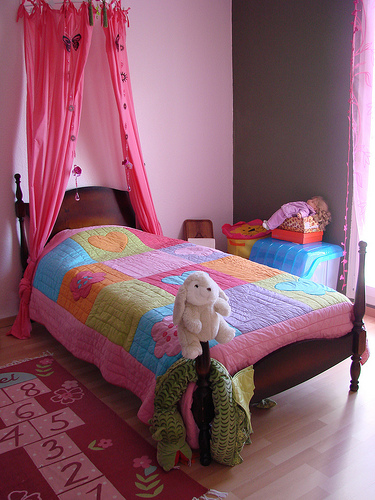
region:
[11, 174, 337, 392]
bed for a girl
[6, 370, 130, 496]
hopscotch pattern on carpet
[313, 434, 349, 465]
the floor is wood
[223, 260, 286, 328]
blanket on the bed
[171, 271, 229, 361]
bunny on the bed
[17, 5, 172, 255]
canopy over the bed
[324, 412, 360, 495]
reflection on the floor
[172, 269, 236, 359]
Stuffed rabbit on the bed leg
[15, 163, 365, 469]
Bed set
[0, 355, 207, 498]
Dark red carpet with several numbers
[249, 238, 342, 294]
Small toy box next to the bed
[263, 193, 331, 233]
Stuffed toys on top of the toy box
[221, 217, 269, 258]
Yellow basket next to the toy box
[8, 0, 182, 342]
Pink curtain on top of the bed head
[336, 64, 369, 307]
Window next to the bed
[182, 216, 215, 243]
Wooden chair next to the bed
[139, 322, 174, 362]
square on the quilt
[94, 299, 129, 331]
square on the quilt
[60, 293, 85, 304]
square on the quilt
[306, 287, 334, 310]
square on the quilt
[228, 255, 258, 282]
square on the quilt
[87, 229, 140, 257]
square on the quilt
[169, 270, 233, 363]
the bunny on the bed leg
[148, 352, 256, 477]
the stuffed animal in the frame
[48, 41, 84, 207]
the beads hanging from the ceiling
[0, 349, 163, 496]
the rug on the ground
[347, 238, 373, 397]
the wooden leg of the bed frame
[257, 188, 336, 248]
the doll on the shoebox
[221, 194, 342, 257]
the toys in th corner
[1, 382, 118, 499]
the numbers on the rug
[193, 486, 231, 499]
the white frills on the edgde of the rug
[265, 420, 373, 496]
the wooden floorboards for the room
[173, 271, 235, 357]
A white, stuffed bunny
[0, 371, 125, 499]
A hopscotch pattern on a rug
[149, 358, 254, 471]
A green, stuffed dragon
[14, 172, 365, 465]
A bed with a dark-brown, wooden frame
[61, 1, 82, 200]
A string of adornments hanging from the ceiling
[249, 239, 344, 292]
A plastic container with a blue lid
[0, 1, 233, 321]
A light pink wall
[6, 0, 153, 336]
Hot pink drapes above the bed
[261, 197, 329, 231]
A toy doll with light brown hair and pink clothes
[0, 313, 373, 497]
Wooden floorboards cover the floor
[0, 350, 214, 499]
red rug with pink flowers and green leaves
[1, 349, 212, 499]
red rug with pink and red hopscotch design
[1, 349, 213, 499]
red and pink rug with white fringe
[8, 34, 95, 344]
pink curtain tied in a large knot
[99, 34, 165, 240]
pink curtain with a black butterfly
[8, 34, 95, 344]
pink curtain with a black butterfly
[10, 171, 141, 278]
brown wooden headboard behind the pink curtains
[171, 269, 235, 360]
tan stuffed bunny sitting on a wooden bedpost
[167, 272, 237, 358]
white stuffed bunny toy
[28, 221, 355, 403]
bedspread on the bed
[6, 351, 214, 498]
rug on the floor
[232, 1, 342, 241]
dark grey wall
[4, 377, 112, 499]
numbers on the rug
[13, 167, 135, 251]
headboard of the bed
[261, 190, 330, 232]
baby doll wearing pink pajamas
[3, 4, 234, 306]
light pink wall behind the bed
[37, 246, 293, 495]
a scene during the day time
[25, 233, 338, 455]
a colorful bed